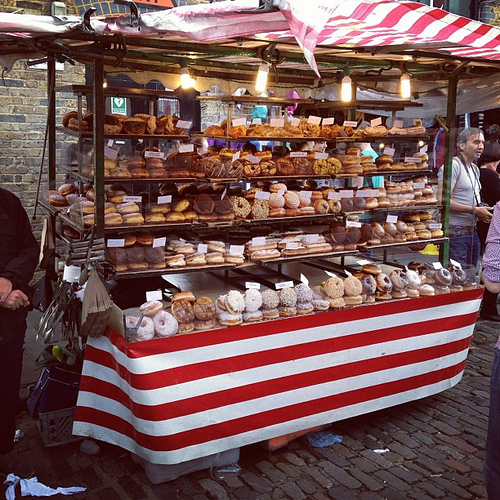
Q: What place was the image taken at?
A: It was taken at the kiosk.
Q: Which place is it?
A: It is a kiosk.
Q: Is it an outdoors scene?
A: Yes, it is outdoors.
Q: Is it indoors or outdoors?
A: It is outdoors.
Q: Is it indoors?
A: No, it is outdoors.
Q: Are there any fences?
A: No, there are no fences.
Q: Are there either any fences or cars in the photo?
A: No, there are no fences or cars.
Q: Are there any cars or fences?
A: No, there are no fences or cars.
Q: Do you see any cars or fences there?
A: No, there are no fences or cars.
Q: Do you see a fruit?
A: No, there are no fruits.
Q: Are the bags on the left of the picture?
A: Yes, the bags are on the left of the image.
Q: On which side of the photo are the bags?
A: The bags are on the left of the image.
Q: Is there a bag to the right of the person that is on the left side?
A: Yes, there are bags to the right of the person.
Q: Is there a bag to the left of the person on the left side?
A: No, the bags are to the right of the person.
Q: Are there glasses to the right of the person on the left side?
A: No, there are bags to the right of the person.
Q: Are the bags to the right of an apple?
A: No, the bags are to the right of the person.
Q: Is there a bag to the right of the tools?
A: Yes, there are bags to the right of the tools.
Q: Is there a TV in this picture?
A: No, there are no televisions.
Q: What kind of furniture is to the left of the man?
A: The pieces of furniture are shelves.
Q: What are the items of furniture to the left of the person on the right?
A: The pieces of furniture are shelves.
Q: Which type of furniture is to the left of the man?
A: The pieces of furniture are shelves.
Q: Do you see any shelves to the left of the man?
A: Yes, there are shelves to the left of the man.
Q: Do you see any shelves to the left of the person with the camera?
A: Yes, there are shelves to the left of the man.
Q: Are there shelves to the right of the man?
A: No, the shelves are to the left of the man.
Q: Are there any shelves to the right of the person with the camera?
A: No, the shelves are to the left of the man.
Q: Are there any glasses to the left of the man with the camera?
A: No, there are shelves to the left of the man.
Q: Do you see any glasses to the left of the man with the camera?
A: No, there are shelves to the left of the man.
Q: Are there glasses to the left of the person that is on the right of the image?
A: No, there are shelves to the left of the man.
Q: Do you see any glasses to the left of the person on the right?
A: No, there are shelves to the left of the man.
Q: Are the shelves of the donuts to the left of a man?
A: Yes, the shelves are to the left of a man.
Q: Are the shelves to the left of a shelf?
A: No, the shelves are to the left of a man.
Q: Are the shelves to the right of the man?
A: No, the shelves are to the left of the man.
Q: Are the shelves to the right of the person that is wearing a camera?
A: No, the shelves are to the left of the man.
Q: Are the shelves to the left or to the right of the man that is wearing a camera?
A: The shelves are to the left of the man.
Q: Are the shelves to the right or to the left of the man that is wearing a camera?
A: The shelves are to the left of the man.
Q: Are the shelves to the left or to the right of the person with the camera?
A: The shelves are to the left of the man.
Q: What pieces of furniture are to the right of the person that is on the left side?
A: The pieces of furniture are shelves.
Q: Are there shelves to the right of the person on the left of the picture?
A: Yes, there are shelves to the right of the person.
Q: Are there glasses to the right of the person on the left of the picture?
A: No, there are shelves to the right of the person.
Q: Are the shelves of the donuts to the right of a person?
A: Yes, the shelves are to the right of a person.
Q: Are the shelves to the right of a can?
A: No, the shelves are to the right of a person.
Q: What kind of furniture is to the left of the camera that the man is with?
A: The pieces of furniture are shelves.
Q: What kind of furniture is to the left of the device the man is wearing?
A: The pieces of furniture are shelves.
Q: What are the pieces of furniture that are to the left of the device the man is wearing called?
A: The pieces of furniture are shelves.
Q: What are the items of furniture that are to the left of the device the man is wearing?
A: The pieces of furniture are shelves.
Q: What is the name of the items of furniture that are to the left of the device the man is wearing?
A: The pieces of furniture are shelves.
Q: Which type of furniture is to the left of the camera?
A: The pieces of furniture are shelves.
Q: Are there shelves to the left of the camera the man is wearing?
A: Yes, there are shelves to the left of the camera.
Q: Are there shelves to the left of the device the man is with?
A: Yes, there are shelves to the left of the camera.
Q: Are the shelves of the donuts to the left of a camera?
A: Yes, the shelves are to the left of a camera.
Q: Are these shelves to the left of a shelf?
A: No, the shelves are to the left of a camera.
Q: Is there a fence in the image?
A: No, there are no fences.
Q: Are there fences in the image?
A: No, there are no fences.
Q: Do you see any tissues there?
A: No, there are no tissues.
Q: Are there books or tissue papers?
A: No, there are no tissue papers or books.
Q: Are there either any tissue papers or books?
A: No, there are no tissue papers or books.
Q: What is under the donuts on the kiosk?
A: The trash is under the doughnuts.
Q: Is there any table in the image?
A: Yes, there is a table.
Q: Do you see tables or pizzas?
A: Yes, there is a table.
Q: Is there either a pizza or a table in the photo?
A: Yes, there is a table.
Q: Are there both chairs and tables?
A: No, there is a table but no chairs.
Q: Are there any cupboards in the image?
A: No, there are no cupboards.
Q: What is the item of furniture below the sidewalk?
A: The piece of furniture is a table.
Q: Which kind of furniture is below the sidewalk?
A: The piece of furniture is a table.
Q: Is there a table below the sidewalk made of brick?
A: Yes, there is a table below the sidewalk.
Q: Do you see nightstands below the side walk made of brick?
A: No, there is a table below the side walk.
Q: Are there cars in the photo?
A: No, there are no cars.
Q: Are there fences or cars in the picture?
A: No, there are no cars or fences.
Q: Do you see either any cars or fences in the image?
A: No, there are no cars or fences.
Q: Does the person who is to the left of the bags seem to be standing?
A: Yes, the person is standing.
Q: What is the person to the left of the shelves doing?
A: The person is standing.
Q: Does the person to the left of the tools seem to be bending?
A: No, the person is standing.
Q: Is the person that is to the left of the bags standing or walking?
A: The person is standing.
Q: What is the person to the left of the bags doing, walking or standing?
A: The person is standing.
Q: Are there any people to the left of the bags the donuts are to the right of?
A: Yes, there is a person to the left of the bags.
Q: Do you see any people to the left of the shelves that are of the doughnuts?
A: Yes, there is a person to the left of the shelves.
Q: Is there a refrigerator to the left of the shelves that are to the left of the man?
A: No, there is a person to the left of the shelves.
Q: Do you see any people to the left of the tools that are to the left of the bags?
A: Yes, there is a person to the left of the tools.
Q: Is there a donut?
A: Yes, there are donuts.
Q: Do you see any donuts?
A: Yes, there are donuts.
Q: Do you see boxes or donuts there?
A: Yes, there are donuts.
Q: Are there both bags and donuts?
A: Yes, there are both donuts and a bag.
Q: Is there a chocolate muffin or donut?
A: Yes, there are chocolate donuts.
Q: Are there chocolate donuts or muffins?
A: Yes, there are chocolate donuts.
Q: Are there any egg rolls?
A: No, there are no egg rolls.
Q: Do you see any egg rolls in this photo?
A: No, there are no egg rolls.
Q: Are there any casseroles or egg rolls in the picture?
A: No, there are no egg rolls or casseroles.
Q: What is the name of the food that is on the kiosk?
A: The food is donuts.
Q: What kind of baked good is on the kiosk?
A: The food is donuts.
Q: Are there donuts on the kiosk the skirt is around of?
A: Yes, there are donuts on the kiosk.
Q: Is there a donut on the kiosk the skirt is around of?
A: Yes, there are donuts on the kiosk.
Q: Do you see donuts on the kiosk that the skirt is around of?
A: Yes, there are donuts on the kiosk.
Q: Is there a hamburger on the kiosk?
A: No, there are donuts on the kiosk.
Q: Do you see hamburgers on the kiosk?
A: No, there are donuts on the kiosk.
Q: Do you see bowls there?
A: No, there are no bowls.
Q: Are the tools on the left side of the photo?
A: Yes, the tools are on the left of the image.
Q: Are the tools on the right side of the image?
A: No, the tools are on the left of the image.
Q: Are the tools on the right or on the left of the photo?
A: The tools are on the left of the image.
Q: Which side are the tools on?
A: The tools are on the left of the image.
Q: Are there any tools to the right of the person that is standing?
A: Yes, there are tools to the right of the person.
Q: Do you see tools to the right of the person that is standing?
A: Yes, there are tools to the right of the person.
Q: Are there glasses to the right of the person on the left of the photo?
A: No, there are tools to the right of the person.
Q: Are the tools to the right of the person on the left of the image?
A: Yes, the tools are to the right of the person.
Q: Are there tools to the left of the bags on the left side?
A: Yes, there are tools to the left of the bags.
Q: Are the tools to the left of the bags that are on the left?
A: Yes, the tools are to the left of the bags.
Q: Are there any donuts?
A: Yes, there are donuts.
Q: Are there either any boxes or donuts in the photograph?
A: Yes, there are donuts.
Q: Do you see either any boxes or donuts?
A: Yes, there are donuts.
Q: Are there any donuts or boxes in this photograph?
A: Yes, there are donuts.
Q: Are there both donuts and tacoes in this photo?
A: No, there are donuts but no tacoes.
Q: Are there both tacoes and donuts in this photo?
A: No, there are donuts but no tacoes.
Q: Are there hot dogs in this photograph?
A: No, there are no hot dogs.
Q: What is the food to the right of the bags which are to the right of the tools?
A: The food is donuts.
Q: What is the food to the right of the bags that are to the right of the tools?
A: The food is donuts.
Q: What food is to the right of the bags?
A: The food is donuts.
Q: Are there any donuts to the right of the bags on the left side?
A: Yes, there are donuts to the right of the bags.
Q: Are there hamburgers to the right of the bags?
A: No, there are donuts to the right of the bags.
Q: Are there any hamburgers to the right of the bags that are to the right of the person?
A: No, there are donuts to the right of the bags.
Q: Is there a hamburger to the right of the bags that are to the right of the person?
A: No, there are donuts to the right of the bags.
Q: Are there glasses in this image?
A: No, there are no glasses.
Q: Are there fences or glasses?
A: No, there are no glasses or fences.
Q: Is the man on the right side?
A: Yes, the man is on the right of the image.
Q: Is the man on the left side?
A: No, the man is on the right of the image.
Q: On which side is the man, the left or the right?
A: The man is on the right of the image.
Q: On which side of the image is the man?
A: The man is on the right of the image.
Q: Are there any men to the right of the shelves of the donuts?
A: Yes, there is a man to the right of the shelves.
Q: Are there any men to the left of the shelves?
A: No, the man is to the right of the shelves.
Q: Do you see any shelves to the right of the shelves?
A: No, there is a man to the right of the shelves.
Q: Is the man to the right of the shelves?
A: Yes, the man is to the right of the shelves.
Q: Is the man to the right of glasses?
A: No, the man is to the right of the shelves.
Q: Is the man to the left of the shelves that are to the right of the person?
A: No, the man is to the right of the shelves.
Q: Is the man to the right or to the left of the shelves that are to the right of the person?
A: The man is to the right of the shelves.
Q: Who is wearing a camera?
A: The man is wearing a camera.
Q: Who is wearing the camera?
A: The man is wearing a camera.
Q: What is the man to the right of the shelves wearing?
A: The man is wearing a camera.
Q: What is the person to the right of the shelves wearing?
A: The man is wearing a camera.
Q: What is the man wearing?
A: The man is wearing a camera.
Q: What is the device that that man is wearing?
A: The device is a camera.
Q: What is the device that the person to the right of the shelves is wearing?
A: The device is a camera.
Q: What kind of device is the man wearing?
A: The man is wearing a camera.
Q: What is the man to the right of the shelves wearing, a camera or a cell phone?
A: The man is wearing a camera.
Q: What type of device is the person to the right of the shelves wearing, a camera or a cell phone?
A: The man is wearing a camera.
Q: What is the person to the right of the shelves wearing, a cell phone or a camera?
A: The man is wearing a camera.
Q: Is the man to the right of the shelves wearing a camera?
A: Yes, the man is wearing a camera.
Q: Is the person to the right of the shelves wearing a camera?
A: Yes, the man is wearing a camera.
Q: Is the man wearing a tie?
A: No, the man is wearing a camera.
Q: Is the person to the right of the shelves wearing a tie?
A: No, the man is wearing a camera.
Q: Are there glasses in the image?
A: No, there are no glasses.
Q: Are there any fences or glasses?
A: No, there are no glasses or fences.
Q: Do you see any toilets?
A: No, there are no toilets.